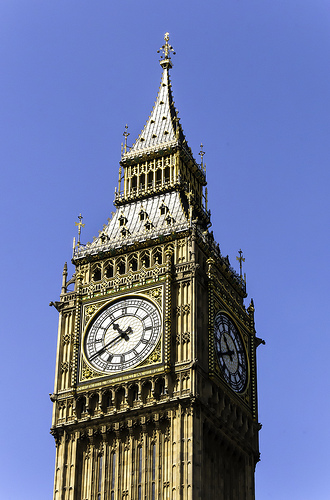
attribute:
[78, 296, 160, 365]
clock — round, analog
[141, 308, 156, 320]
numeral — roman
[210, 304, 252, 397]
clock — large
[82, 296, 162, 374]
clock — large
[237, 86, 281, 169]
sky — blue, cloudless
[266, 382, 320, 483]
sky — blue, cloudless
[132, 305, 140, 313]
roman numeral — 1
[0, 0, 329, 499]
sky — cloudless, blue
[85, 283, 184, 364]
clock — analog, round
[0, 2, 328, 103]
sky — cloudless, blue